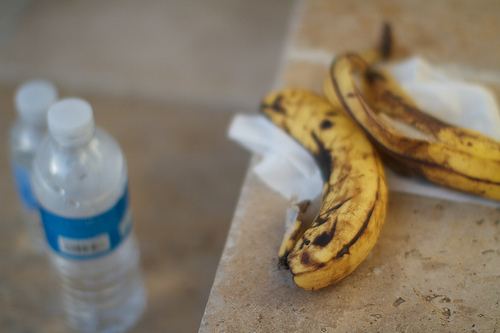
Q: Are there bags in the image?
A: Yes, there is a bag.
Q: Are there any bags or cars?
A: Yes, there is a bag.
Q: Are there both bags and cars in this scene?
A: No, there is a bag but no cars.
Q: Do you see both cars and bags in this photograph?
A: No, there is a bag but no cars.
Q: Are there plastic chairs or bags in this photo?
A: Yes, there is a plastic bag.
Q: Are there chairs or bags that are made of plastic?
A: Yes, the bag is made of plastic.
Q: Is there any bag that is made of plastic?
A: Yes, there is a bag that is made of plastic.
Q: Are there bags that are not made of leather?
A: Yes, there is a bag that is made of plastic.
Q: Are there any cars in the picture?
A: No, there are no cars.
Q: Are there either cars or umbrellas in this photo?
A: No, there are no cars or umbrellas.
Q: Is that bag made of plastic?
A: Yes, the bag is made of plastic.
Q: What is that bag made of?
A: The bag is made of plastic.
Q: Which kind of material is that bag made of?
A: The bag is made of plastic.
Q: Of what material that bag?
A: The bag is made of plastic.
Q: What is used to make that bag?
A: The bag is made of plastic.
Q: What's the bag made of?
A: The bag is made of plastic.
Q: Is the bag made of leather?
A: No, the bag is made of plastic.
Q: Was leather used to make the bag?
A: No, the bag is made of plastic.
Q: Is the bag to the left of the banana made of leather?
A: No, the bag is made of plastic.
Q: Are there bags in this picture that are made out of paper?
A: No, there is a bag but it is made of plastic.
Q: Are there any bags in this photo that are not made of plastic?
A: No, there is a bag but it is made of plastic.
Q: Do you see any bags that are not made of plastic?
A: No, there is a bag but it is made of plastic.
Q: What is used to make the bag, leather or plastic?
A: The bag is made of plastic.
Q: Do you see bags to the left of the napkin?
A: Yes, there is a bag to the left of the napkin.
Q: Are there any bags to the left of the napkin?
A: Yes, there is a bag to the left of the napkin.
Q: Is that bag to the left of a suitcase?
A: No, the bag is to the left of the napkin.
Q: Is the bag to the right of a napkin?
A: No, the bag is to the left of a napkin.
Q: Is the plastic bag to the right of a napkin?
A: No, the bag is to the left of a napkin.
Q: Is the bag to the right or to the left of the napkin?
A: The bag is to the left of the napkin.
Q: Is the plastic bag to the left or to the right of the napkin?
A: The bag is to the left of the napkin.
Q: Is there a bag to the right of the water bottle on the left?
A: Yes, there is a bag to the right of the water bottle.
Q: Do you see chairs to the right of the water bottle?
A: No, there is a bag to the right of the water bottle.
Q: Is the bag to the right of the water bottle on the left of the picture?
A: Yes, the bag is to the right of the water bottle.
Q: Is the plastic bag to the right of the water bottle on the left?
A: Yes, the bag is to the right of the water bottle.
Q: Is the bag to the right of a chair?
A: No, the bag is to the right of the water bottle.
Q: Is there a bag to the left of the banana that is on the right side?
A: Yes, there is a bag to the left of the banana.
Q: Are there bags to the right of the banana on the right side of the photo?
A: No, the bag is to the left of the banana.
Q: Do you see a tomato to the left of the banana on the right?
A: No, there is a bag to the left of the banana.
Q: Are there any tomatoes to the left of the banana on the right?
A: No, there is a bag to the left of the banana.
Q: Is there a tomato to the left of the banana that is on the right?
A: No, there is a bag to the left of the banana.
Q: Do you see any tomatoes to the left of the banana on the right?
A: No, there is a bag to the left of the banana.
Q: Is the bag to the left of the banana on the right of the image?
A: Yes, the bag is to the left of the banana.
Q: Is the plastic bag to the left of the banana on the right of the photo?
A: Yes, the bag is to the left of the banana.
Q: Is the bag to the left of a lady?
A: No, the bag is to the left of the banana.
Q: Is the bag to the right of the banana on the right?
A: No, the bag is to the left of the banana.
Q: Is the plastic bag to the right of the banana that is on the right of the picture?
A: No, the bag is to the left of the banana.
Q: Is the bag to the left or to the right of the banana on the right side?
A: The bag is to the left of the banana.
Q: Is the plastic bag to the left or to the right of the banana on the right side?
A: The bag is to the left of the banana.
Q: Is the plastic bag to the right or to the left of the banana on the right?
A: The bag is to the left of the banana.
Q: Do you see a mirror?
A: No, there are no mirrors.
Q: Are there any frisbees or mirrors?
A: No, there are no mirrors or frisbees.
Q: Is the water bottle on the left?
A: Yes, the water bottle is on the left of the image.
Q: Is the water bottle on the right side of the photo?
A: No, the water bottle is on the left of the image.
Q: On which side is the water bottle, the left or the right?
A: The water bottle is on the left of the image.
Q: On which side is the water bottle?
A: The water bottle is on the left of the image.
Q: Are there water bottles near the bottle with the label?
A: Yes, there is a water bottle near the bottle.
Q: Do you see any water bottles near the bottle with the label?
A: Yes, there is a water bottle near the bottle.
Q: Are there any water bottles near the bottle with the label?
A: Yes, there is a water bottle near the bottle.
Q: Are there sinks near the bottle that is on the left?
A: No, there is a water bottle near the bottle.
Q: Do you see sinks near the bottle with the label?
A: No, there is a water bottle near the bottle.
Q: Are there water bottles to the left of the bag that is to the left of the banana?
A: Yes, there is a water bottle to the left of the bag.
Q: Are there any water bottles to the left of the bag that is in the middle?
A: Yes, there is a water bottle to the left of the bag.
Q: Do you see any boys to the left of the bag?
A: No, there is a water bottle to the left of the bag.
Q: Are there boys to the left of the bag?
A: No, there is a water bottle to the left of the bag.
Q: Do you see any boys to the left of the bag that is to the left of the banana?
A: No, there is a water bottle to the left of the bag.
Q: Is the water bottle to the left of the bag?
A: Yes, the water bottle is to the left of the bag.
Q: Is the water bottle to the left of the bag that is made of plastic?
A: Yes, the water bottle is to the left of the bag.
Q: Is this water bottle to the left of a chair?
A: No, the water bottle is to the left of the bag.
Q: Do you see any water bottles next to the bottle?
A: Yes, there is a water bottle next to the bottle.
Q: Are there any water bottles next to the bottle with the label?
A: Yes, there is a water bottle next to the bottle.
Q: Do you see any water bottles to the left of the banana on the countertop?
A: Yes, there is a water bottle to the left of the banana.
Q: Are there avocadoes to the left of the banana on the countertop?
A: No, there is a water bottle to the left of the banana.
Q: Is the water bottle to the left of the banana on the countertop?
A: Yes, the water bottle is to the left of the banana.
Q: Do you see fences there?
A: No, there are no fences.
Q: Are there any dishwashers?
A: No, there are no dishwashers.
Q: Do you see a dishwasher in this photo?
A: No, there are no dishwashers.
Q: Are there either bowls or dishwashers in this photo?
A: No, there are no dishwashers or bowls.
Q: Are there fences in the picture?
A: No, there are no fences.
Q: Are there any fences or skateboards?
A: No, there are no fences or skateboards.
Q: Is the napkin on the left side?
A: No, the napkin is on the right of the image.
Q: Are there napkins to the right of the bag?
A: Yes, there is a napkin to the right of the bag.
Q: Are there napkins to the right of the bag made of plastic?
A: Yes, there is a napkin to the right of the bag.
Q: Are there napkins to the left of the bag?
A: No, the napkin is to the right of the bag.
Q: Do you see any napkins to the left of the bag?
A: No, the napkin is to the right of the bag.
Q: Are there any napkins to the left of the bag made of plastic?
A: No, the napkin is to the right of the bag.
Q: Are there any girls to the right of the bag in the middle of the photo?
A: No, there is a napkin to the right of the bag.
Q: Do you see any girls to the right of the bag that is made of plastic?
A: No, there is a napkin to the right of the bag.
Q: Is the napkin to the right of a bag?
A: Yes, the napkin is to the right of a bag.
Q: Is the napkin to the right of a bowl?
A: No, the napkin is to the right of a bag.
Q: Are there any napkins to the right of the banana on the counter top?
A: Yes, there is a napkin to the right of the banana.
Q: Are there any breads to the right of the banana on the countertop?
A: No, there is a napkin to the right of the banana.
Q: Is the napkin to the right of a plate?
A: No, the napkin is to the right of the banana.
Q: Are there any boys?
A: No, there are no boys.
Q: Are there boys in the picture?
A: No, there are no boys.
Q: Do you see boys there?
A: No, there are no boys.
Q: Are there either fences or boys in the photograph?
A: No, there are no boys or fences.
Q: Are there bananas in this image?
A: Yes, there is a banana.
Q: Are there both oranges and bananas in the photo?
A: No, there is a banana but no oranges.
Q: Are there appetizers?
A: No, there are no appetizers.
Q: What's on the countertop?
A: The banana is on the countertop.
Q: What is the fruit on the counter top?
A: The fruit is a banana.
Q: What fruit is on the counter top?
A: The fruit is a banana.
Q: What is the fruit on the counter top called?
A: The fruit is a banana.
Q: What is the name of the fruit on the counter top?
A: The fruit is a banana.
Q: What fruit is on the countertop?
A: The fruit is a banana.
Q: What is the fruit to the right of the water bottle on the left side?
A: The fruit is a banana.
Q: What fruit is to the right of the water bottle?
A: The fruit is a banana.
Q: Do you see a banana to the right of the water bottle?
A: Yes, there is a banana to the right of the water bottle.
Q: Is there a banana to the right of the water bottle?
A: Yes, there is a banana to the right of the water bottle.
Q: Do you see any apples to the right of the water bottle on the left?
A: No, there is a banana to the right of the water bottle.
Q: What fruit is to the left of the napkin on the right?
A: The fruit is a banana.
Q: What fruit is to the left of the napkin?
A: The fruit is a banana.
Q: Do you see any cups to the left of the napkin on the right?
A: No, there is a banana to the left of the napkin.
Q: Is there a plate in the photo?
A: No, there are no plates.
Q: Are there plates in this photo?
A: No, there are no plates.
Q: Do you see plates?
A: No, there are no plates.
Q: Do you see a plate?
A: No, there are no plates.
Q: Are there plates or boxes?
A: No, there are no plates or boxes.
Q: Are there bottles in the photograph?
A: Yes, there is a bottle.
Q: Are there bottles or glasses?
A: Yes, there is a bottle.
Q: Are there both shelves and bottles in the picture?
A: No, there is a bottle but no shelves.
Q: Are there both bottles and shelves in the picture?
A: No, there is a bottle but no shelves.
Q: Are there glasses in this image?
A: No, there are no glasses.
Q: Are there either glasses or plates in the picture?
A: No, there are no glasses or plates.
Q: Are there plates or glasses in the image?
A: No, there are no glasses or plates.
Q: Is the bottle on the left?
A: Yes, the bottle is on the left of the image.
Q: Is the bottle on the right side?
A: No, the bottle is on the left of the image.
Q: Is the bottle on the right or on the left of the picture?
A: The bottle is on the left of the image.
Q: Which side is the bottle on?
A: The bottle is on the left of the image.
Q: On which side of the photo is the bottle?
A: The bottle is on the left of the image.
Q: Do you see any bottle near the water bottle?
A: Yes, there is a bottle near the water bottle.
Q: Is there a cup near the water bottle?
A: No, there is a bottle near the water bottle.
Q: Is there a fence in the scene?
A: No, there are no fences.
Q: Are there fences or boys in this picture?
A: No, there are no fences or boys.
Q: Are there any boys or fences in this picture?
A: No, there are no fences or boys.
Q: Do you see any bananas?
A: Yes, there is a banana.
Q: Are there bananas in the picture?
A: Yes, there is a banana.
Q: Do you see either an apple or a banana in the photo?
A: Yes, there is a banana.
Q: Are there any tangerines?
A: No, there are no tangerines.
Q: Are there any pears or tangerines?
A: No, there are no tangerines or pears.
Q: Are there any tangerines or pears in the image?
A: No, there are no tangerines or pears.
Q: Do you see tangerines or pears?
A: No, there are no tangerines or pears.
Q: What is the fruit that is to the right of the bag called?
A: The fruit is a banana.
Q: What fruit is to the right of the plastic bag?
A: The fruit is a banana.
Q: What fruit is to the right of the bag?
A: The fruit is a banana.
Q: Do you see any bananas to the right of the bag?
A: Yes, there is a banana to the right of the bag.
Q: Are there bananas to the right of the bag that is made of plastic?
A: Yes, there is a banana to the right of the bag.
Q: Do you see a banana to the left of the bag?
A: No, the banana is to the right of the bag.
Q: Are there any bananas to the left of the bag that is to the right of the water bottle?
A: No, the banana is to the right of the bag.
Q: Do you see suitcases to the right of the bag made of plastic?
A: No, there is a banana to the right of the bag.